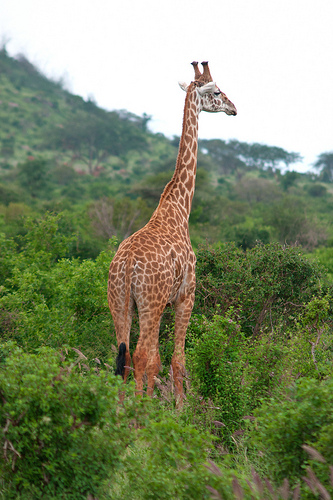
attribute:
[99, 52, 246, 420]
giraffe — standing, tall, spotted, two colors, walking, in area, brown, white, looking, in wild, among weeds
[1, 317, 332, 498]
weeds — green, growing, tall, lush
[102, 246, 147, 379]
tail — hair, long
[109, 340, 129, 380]
hair — black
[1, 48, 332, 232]
terrain — hilly, hill, green, distance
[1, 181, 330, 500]
field — weeds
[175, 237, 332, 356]
bushes — area, green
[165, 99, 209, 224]
neck — long, skinny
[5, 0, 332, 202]
sky — overcast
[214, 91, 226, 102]
eye — open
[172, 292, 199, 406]
leg — long